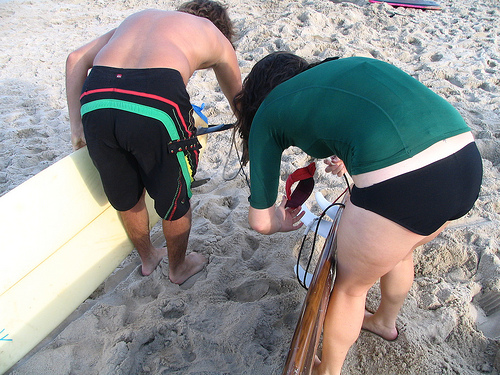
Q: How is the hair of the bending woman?
A: Brown.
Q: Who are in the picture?
A: Two people with surfboards.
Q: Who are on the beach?
A: Two people.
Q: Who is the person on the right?
A: A woman.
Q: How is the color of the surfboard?
A: White.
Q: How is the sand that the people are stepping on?
A: Brown.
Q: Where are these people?
A: The beach.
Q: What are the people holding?
A: Surfboards.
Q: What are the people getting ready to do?
A: Surf.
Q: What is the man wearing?
A: Swim trunks.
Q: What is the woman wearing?
A: A green shirt and a bikini bottom.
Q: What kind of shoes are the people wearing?
A: They are barefoot.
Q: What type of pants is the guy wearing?
A: Shorts.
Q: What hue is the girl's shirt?
A: Green.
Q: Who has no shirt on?
A: The man.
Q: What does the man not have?
A: No shirt.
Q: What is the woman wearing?
A: Shirt.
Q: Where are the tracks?
A: On the sand.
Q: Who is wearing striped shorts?
A: A man.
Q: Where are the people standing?
A: On the sand.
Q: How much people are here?
A: 2.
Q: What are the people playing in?
A: Sand.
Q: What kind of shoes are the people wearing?
A: Barefoot.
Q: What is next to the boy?
A: Surfboard.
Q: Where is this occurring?
A: Beach.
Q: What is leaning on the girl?
A: Surfboard.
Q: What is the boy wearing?
A: Shorts.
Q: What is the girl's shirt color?
A: Green.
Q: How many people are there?
A: Two.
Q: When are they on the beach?
A: Daytime.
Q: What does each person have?
A: Surfboard.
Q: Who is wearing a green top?
A: The woman.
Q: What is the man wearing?
A: Swim trunks.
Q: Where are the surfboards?
A: On the sand.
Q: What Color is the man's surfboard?
A: Yellow.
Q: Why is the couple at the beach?
A: To surf.